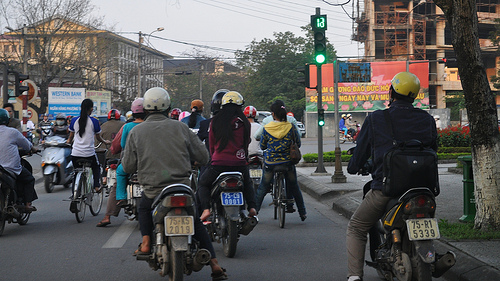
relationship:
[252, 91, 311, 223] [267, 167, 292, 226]
woman on bike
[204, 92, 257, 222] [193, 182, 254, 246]
couple on motorcycle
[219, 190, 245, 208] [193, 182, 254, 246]
plate on motorcycle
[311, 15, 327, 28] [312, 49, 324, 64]
numbers above light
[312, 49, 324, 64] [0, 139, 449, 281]
light near road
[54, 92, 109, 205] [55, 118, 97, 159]
woman has shirt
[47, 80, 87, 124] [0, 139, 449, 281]
sign on road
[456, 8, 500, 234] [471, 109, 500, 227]
tree has trunk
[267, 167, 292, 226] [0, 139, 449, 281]
bike on road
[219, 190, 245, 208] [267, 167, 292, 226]
plate on bike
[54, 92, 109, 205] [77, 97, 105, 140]
woman has hair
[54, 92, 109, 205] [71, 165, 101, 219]
woman on bike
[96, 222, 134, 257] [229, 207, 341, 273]
line on road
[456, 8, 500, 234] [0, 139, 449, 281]
tree near road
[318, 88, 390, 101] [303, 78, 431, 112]
writing on sign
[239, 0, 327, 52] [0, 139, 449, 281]
wires above road